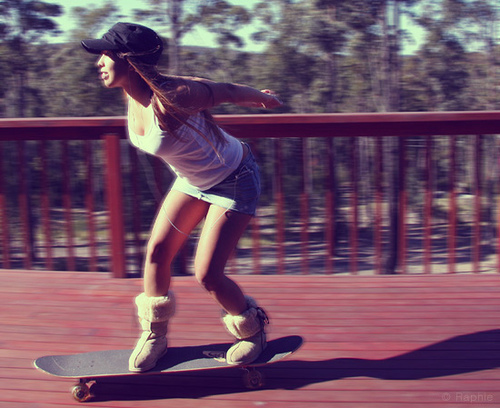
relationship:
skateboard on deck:
[80, 326, 312, 404] [269, 286, 466, 404]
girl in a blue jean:
[94, 17, 280, 373] [170, 139, 265, 220]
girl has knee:
[94, 17, 280, 373] [198, 263, 222, 295]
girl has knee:
[94, 17, 280, 373] [145, 237, 172, 264]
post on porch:
[469, 132, 492, 271] [13, 112, 497, 400]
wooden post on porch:
[58, 139, 75, 267] [2, 265, 497, 406]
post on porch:
[12, 136, 34, 266] [13, 112, 497, 400]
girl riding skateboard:
[94, 24, 278, 371] [38, 332, 300, 387]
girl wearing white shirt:
[94, 17, 280, 373] [129, 114, 249, 179]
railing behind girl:
[2, 113, 495, 279] [94, 17, 280, 373]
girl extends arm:
[94, 17, 280, 373] [164, 69, 287, 121]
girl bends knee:
[94, 17, 280, 373] [145, 237, 172, 264]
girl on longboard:
[94, 17, 280, 373] [36, 323, 318, 385]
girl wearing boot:
[94, 17, 280, 373] [123, 292, 180, 373]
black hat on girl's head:
[63, 22, 166, 63] [91, 51, 165, 98]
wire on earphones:
[148, 212, 210, 242] [117, 52, 131, 64]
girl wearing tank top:
[94, 17, 280, 373] [129, 76, 226, 183]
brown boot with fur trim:
[219, 297, 271, 364] [220, 308, 262, 338]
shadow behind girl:
[91, 325, 499, 402] [94, 17, 280, 373]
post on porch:
[343, 142, 363, 279] [245, 134, 499, 365]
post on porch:
[343, 142, 363, 279] [13, 112, 497, 400]